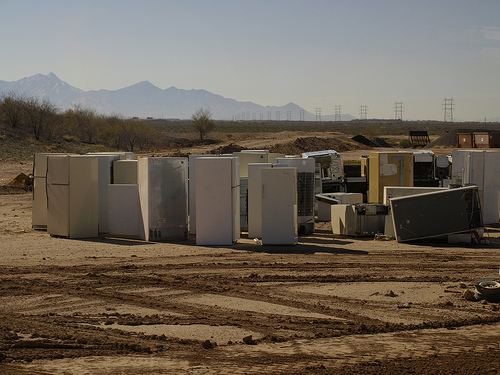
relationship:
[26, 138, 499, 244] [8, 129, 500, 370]
fridges in a junk yard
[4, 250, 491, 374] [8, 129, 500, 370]
tire tracks in junk yard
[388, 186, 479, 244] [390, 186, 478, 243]
back of back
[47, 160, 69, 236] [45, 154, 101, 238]
front of a fridge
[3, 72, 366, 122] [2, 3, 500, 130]
mountains in background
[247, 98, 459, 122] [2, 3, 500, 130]
power poles in background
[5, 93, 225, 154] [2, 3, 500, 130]
trees in background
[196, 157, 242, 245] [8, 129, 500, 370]
fridge in junk yard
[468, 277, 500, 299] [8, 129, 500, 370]
wheel in junk yard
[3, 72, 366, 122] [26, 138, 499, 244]
mountains behind fridges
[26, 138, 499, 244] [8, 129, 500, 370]
fridges in junk yard